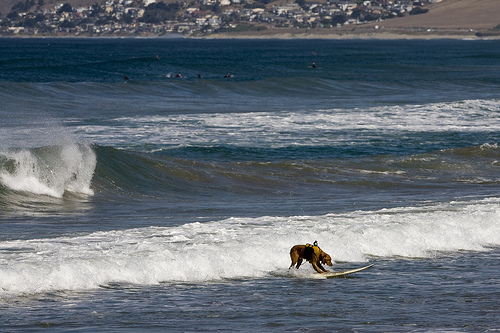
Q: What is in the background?
A: A town on the beach.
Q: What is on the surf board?
A: A dog.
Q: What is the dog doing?
A: Surfing.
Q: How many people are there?
A: 1.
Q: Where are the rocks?
A: Beside the water.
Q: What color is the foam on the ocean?
A: White.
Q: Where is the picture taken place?
A: At the ocean.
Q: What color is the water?
A: Blue.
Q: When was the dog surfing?
A: During the day.